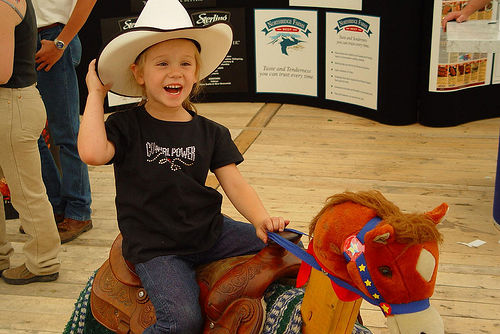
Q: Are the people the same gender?
A: No, they are both male and female.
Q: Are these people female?
A: No, they are both male and female.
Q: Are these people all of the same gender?
A: No, they are both male and female.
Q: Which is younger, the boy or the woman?
A: The boy is younger than the woman.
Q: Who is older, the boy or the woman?
A: The woman is older than the boy.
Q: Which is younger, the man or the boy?
A: The boy is younger than the man.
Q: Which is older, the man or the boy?
A: The man is older than the boy.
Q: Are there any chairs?
A: No, there are no chairs.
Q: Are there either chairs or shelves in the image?
A: No, there are no chairs or shelves.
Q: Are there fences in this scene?
A: No, there are no fences.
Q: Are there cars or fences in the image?
A: No, there are no fences or cars.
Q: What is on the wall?
A: The sign is on the wall.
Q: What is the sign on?
A: The sign is on the wall.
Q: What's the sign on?
A: The sign is on the wall.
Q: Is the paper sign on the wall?
A: Yes, the sign is on the wall.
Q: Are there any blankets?
A: Yes, there is a blanket.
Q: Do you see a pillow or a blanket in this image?
A: Yes, there is a blanket.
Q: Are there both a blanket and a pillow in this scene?
A: No, there is a blanket but no pillows.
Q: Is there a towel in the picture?
A: No, there are no towels.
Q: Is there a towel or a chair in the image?
A: No, there are no towels or chairs.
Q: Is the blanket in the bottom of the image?
A: Yes, the blanket is in the bottom of the image.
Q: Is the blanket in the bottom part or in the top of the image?
A: The blanket is in the bottom of the image.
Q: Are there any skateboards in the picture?
A: No, there are no skateboards.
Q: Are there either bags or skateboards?
A: No, there are no skateboards or bags.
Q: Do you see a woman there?
A: Yes, there is a woman.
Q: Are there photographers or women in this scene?
A: Yes, there is a woman.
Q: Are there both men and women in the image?
A: Yes, there are both a woman and a man.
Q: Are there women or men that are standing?
A: Yes, the woman is standing.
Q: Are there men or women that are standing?
A: Yes, the woman is standing.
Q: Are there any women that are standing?
A: Yes, there is a woman that is standing.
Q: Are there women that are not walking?
A: Yes, there is a woman that is standing.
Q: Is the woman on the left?
A: Yes, the woman is on the left of the image.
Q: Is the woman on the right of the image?
A: No, the woman is on the left of the image.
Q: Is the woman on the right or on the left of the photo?
A: The woman is on the left of the image.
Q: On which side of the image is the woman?
A: The woman is on the left of the image.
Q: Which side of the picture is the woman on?
A: The woman is on the left of the image.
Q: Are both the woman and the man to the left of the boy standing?
A: Yes, both the woman and the man are standing.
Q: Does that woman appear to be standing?
A: Yes, the woman is standing.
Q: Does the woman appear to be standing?
A: Yes, the woman is standing.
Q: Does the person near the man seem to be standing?
A: Yes, the woman is standing.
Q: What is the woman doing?
A: The woman is standing.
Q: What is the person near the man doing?
A: The woman is standing.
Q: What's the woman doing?
A: The woman is standing.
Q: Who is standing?
A: The woman is standing.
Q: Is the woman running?
A: No, the woman is standing.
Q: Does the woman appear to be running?
A: No, the woman is standing.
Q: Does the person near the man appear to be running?
A: No, the woman is standing.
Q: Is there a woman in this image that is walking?
A: No, there is a woman but she is standing.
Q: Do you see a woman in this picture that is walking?
A: No, there is a woman but she is standing.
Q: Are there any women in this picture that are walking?
A: No, there is a woman but she is standing.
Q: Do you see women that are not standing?
A: No, there is a woman but she is standing.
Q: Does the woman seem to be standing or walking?
A: The woman is standing.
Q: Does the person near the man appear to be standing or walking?
A: The woman is standing.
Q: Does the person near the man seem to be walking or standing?
A: The woman is standing.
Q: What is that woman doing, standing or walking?
A: The woman is standing.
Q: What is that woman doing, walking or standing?
A: The woman is standing.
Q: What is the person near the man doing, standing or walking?
A: The woman is standing.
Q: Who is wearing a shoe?
A: The woman is wearing a shoe.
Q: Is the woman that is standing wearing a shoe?
A: Yes, the woman is wearing a shoe.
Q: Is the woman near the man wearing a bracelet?
A: No, the woman is wearing a shoe.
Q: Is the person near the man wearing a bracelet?
A: No, the woman is wearing a shoe.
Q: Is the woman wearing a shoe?
A: Yes, the woman is wearing a shoe.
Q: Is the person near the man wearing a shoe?
A: Yes, the woman is wearing a shoe.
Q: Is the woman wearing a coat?
A: No, the woman is wearing a shoe.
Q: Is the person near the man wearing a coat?
A: No, the woman is wearing a shoe.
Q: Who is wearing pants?
A: The woman is wearing pants.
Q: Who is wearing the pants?
A: The woman is wearing pants.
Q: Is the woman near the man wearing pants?
A: Yes, the woman is wearing pants.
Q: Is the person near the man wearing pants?
A: Yes, the woman is wearing pants.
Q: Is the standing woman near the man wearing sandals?
A: No, the woman is wearing pants.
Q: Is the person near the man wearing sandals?
A: No, the woman is wearing pants.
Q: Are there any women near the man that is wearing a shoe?
A: Yes, there is a woman near the man.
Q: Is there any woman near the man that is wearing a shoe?
A: Yes, there is a woman near the man.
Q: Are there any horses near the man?
A: No, there is a woman near the man.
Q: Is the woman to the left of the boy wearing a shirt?
A: Yes, the woman is wearing a shirt.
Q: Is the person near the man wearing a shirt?
A: Yes, the woman is wearing a shirt.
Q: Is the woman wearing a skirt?
A: No, the woman is wearing a shirt.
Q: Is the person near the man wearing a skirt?
A: No, the woman is wearing a shirt.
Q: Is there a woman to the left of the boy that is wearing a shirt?
A: Yes, there is a woman to the left of the boy.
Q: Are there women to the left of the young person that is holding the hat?
A: Yes, there is a woman to the left of the boy.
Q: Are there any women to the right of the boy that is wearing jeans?
A: No, the woman is to the left of the boy.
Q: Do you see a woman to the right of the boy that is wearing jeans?
A: No, the woman is to the left of the boy.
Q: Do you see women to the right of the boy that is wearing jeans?
A: No, the woman is to the left of the boy.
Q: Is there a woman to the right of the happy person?
A: No, the woman is to the left of the boy.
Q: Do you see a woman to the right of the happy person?
A: No, the woman is to the left of the boy.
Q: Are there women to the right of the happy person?
A: No, the woman is to the left of the boy.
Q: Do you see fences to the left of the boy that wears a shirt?
A: No, there is a woman to the left of the boy.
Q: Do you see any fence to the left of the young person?
A: No, there is a woman to the left of the boy.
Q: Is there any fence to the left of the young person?
A: No, there is a woman to the left of the boy.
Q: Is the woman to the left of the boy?
A: Yes, the woman is to the left of the boy.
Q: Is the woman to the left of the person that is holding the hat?
A: Yes, the woman is to the left of the boy.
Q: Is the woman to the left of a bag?
A: No, the woman is to the left of the boy.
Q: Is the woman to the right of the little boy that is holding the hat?
A: No, the woman is to the left of the boy.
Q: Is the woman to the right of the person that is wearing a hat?
A: No, the woman is to the left of the boy.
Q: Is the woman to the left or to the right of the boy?
A: The woman is to the left of the boy.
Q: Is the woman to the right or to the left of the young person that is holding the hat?
A: The woman is to the left of the boy.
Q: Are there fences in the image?
A: No, there are no fences.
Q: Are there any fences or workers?
A: No, there are no fences or workers.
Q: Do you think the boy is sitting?
A: Yes, the boy is sitting.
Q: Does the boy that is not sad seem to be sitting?
A: Yes, the boy is sitting.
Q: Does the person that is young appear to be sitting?
A: Yes, the boy is sitting.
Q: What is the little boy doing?
A: The boy is sitting.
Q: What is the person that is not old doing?
A: The boy is sitting.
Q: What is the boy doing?
A: The boy is sitting.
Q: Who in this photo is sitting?
A: The boy is sitting.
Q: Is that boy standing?
A: No, the boy is sitting.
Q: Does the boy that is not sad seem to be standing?
A: No, the boy is sitting.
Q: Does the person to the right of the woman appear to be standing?
A: No, the boy is sitting.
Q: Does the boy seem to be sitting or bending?
A: The boy is sitting.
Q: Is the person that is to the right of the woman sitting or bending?
A: The boy is sitting.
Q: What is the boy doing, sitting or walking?
A: The boy is sitting.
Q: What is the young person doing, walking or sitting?
A: The boy is sitting.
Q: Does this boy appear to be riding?
A: Yes, the boy is riding.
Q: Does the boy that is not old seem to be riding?
A: Yes, the boy is riding.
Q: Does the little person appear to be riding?
A: Yes, the boy is riding.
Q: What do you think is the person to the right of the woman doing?
A: The boy is riding.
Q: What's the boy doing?
A: The boy is riding.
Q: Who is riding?
A: The boy is riding.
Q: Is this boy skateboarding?
A: No, the boy is riding.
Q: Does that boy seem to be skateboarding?
A: No, the boy is riding.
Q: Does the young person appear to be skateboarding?
A: No, the boy is riding.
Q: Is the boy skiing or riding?
A: The boy is riding.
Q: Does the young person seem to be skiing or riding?
A: The boy is riding.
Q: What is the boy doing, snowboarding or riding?
A: The boy is riding.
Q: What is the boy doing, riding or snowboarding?
A: The boy is riding.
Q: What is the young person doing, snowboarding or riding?
A: The boy is riding.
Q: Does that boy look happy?
A: Yes, the boy is happy.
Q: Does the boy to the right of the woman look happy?
A: Yes, the boy is happy.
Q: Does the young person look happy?
A: Yes, the boy is happy.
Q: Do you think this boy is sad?
A: No, the boy is happy.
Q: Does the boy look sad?
A: No, the boy is happy.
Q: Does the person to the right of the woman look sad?
A: No, the boy is happy.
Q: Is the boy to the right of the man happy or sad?
A: The boy is happy.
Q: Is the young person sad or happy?
A: The boy is happy.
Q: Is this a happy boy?
A: Yes, this is a happy boy.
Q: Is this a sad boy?
A: No, this is a happy boy.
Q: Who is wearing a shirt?
A: The boy is wearing a shirt.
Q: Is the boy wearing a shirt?
A: Yes, the boy is wearing a shirt.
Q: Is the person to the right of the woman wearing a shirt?
A: Yes, the boy is wearing a shirt.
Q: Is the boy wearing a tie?
A: No, the boy is wearing a shirt.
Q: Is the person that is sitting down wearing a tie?
A: No, the boy is wearing a shirt.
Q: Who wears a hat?
A: The boy wears a hat.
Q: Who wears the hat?
A: The boy wears a hat.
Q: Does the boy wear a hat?
A: Yes, the boy wears a hat.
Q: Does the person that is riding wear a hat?
A: Yes, the boy wears a hat.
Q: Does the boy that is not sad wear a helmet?
A: No, the boy wears a hat.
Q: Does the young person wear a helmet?
A: No, the boy wears a hat.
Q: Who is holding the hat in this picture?
A: The boy is holding the hat.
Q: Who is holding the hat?
A: The boy is holding the hat.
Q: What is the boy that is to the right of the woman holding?
A: The boy is holding the hat.